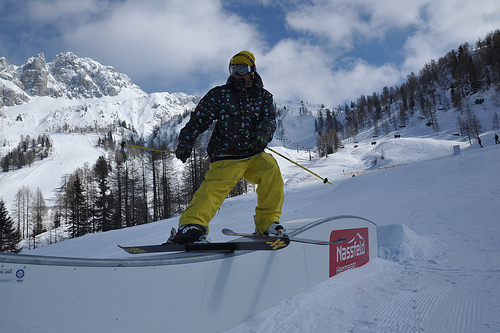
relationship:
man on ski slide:
[175, 50, 288, 245] [0, 200, 376, 298]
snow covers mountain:
[22, 79, 106, 152] [1, 48, 497, 215]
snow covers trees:
[22, 79, 106, 152] [312, 28, 496, 150]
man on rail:
[175, 50, 288, 245] [2, 146, 499, 331]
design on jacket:
[223, 94, 266, 128] [163, 47, 283, 162]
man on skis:
[175, 50, 288, 245] [116, 221, 330, 256]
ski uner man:
[117, 233, 294, 255] [175, 50, 288, 245]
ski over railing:
[117, 233, 294, 255] [0, 214, 380, 331]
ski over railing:
[218, 226, 346, 243] [0, 214, 380, 331]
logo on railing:
[325, 225, 375, 276] [235, 215, 395, 274]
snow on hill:
[59, 169, 486, 318] [0, 142, 492, 327]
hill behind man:
[6, 42, 118, 132] [175, 50, 288, 245]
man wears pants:
[175, 50, 288, 245] [178, 149, 288, 228]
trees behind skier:
[17, 120, 207, 211] [176, 57, 298, 267]